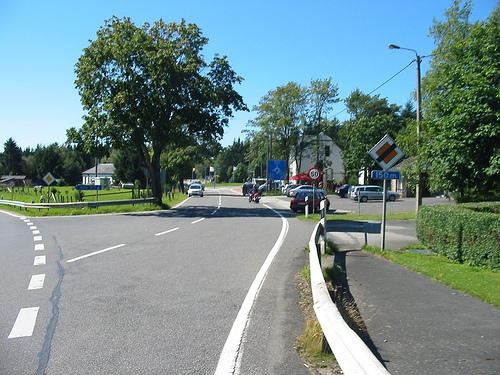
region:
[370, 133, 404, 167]
sign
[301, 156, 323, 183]
sign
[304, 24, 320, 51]
white clouds in blue sky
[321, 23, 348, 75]
white clouds in blue sky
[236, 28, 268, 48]
white clouds in blue sky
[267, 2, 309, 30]
white clouds in blue sky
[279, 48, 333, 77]
white clouds in blue sky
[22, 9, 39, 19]
white clouds in blue sky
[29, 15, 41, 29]
white clouds in blue sky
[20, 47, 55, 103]
white clouds in blue sky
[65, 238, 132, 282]
White line on a road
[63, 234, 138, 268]
Line on a road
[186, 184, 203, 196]
Car in the background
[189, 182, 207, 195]
White car in the background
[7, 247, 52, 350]
Lines in a row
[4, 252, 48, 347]
White lines in a row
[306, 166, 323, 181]
The number "50" is on a sign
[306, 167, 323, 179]
The sign is red and white in color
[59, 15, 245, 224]
A large green tree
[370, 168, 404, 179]
"150m" is written on the sign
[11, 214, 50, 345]
Segmented lines painted on a road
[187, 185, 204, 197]
White vehicle on the road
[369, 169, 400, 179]
A street sign with numbers on it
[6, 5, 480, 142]
A bright, blue clear sky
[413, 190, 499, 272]
Squared bushes lining a yard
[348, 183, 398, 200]
A silver vehicle parked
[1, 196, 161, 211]
Steel barricade of a road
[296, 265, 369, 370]
Patch of grass and dirt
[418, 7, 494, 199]
A tall tree with lots of dark leaves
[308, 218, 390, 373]
The barricade of a road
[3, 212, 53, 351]
white dotted lines in street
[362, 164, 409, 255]
traffic sign on metal pole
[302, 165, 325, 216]
red and white sign on pole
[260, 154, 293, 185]
square blue sign on side of road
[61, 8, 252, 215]
tall geen tree on side of street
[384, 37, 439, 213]
tall street lamp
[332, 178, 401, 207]
cars parked in parking lot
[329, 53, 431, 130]
black power lines in sky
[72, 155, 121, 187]
house in green field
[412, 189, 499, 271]
green hedges on side of street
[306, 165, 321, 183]
sign tells people how fast they can drive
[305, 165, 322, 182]
sign is attached to pole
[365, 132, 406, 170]
sign is attached to pole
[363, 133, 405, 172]
sign is square shaped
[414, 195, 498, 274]
hedge is just off the road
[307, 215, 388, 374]
guard rail protects drivers as well as people on the sidewalk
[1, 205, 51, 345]
line is dotted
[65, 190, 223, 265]
line is dotted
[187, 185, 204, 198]
car is parked on side of road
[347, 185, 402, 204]
car is parked